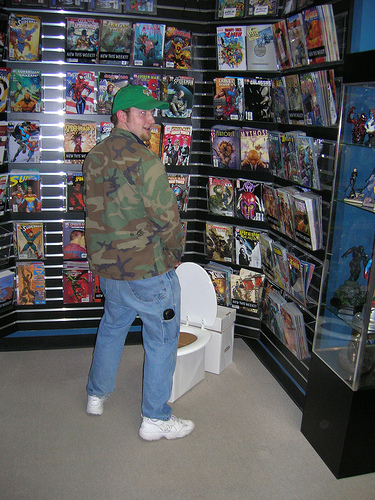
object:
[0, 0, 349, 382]
racks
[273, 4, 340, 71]
comic books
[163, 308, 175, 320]
cellphone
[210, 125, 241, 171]
comic book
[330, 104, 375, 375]
showcase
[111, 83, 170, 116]
cap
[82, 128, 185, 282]
jacket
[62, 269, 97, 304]
spiderman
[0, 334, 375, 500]
ground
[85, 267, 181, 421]
jeans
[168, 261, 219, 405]
toilet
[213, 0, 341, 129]
books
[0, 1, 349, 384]
shelving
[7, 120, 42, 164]
comic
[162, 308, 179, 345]
case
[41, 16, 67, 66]
shelf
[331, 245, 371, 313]
figurine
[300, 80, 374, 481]
glass case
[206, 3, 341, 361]
comic books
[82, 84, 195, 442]
man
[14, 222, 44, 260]
comic book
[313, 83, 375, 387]
glass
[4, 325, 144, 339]
line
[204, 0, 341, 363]
magazines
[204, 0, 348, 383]
shelves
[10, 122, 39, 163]
batman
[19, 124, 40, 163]
superman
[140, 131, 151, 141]
beard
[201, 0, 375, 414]
wall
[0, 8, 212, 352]
wall